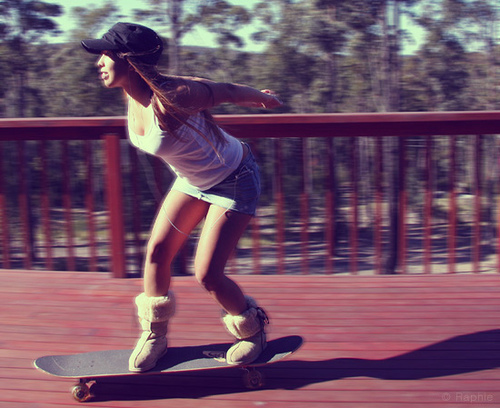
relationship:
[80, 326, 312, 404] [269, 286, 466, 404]
skateboard on deck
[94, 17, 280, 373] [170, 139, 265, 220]
girl in a blue jean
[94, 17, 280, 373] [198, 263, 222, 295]
girl has knee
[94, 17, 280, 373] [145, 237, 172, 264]
girl has knee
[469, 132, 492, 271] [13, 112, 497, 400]
post on porch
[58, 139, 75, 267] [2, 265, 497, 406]
wooden post on porch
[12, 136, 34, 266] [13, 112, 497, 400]
post on porch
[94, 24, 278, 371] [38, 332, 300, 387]
girl riding skateboard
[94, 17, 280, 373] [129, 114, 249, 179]
girl wearing white shirt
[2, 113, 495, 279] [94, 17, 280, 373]
railing behind girl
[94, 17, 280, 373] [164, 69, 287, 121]
girl extends arm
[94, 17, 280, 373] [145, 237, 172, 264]
girl bends knee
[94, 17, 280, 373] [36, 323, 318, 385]
girl on longboard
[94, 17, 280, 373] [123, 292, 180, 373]
girl wearing boot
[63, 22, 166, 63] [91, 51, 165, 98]
black hat on girl's head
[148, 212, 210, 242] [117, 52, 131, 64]
wire on earphones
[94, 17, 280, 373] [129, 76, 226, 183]
girl wearing tank top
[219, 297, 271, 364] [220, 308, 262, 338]
brown boot with fur trim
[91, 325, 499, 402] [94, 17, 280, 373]
shadow behind girl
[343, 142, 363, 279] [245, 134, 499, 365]
post on porch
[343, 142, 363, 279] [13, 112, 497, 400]
post on porch